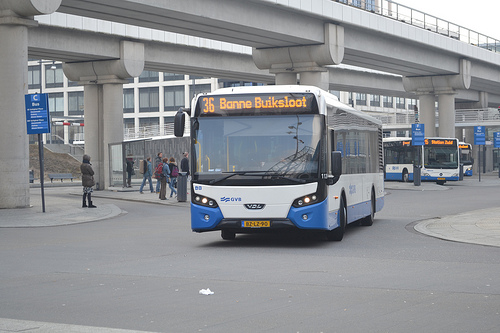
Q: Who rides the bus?
A: Passengers.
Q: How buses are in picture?
A: 3.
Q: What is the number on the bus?
A: 36.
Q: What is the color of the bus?
A: Blue and White.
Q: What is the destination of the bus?
A: Banne Buiksloot.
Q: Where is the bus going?
A: Banne Buiksloot.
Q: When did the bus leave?
A: Just now.